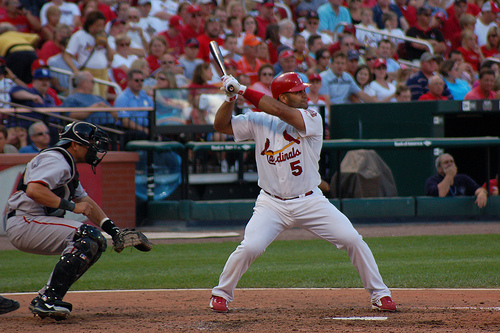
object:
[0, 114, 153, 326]
catcher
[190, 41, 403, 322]
baseball player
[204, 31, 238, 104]
bat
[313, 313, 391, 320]
home plate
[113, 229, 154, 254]
mitt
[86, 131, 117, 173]
mask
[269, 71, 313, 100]
helmet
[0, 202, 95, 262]
pants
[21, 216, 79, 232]
stripe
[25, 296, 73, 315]
shoes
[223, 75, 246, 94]
gloves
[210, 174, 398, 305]
pants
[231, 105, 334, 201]
shirt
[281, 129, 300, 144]
bird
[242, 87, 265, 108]
wrist band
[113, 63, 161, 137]
man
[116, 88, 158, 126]
shirt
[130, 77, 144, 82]
glasses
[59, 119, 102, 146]
helmet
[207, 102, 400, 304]
uniform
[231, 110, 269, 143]
shoulder